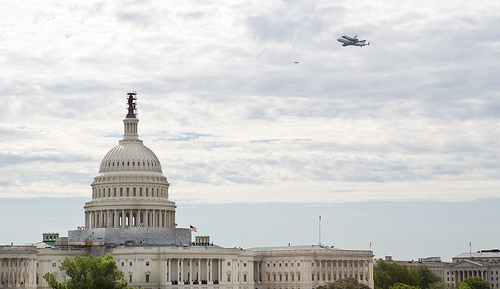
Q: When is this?
A: Daytime.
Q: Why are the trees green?
A: Chlorophyll.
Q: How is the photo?
A: Clear.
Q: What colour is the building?
A: White.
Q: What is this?
A: White house.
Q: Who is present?
A: Nobody.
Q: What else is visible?
A: Clouds.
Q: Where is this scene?
A: Near the Capitol.